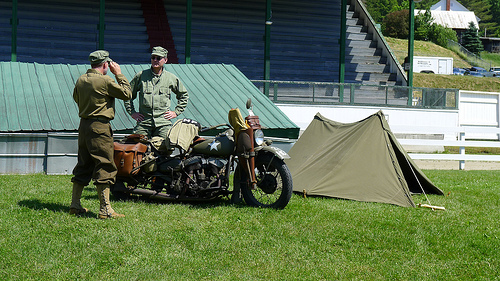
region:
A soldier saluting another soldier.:
[65, 46, 132, 217]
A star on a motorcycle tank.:
[207, 138, 220, 152]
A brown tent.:
[282, 108, 448, 215]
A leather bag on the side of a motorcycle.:
[109, 139, 147, 176]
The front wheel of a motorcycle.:
[241, 141, 292, 210]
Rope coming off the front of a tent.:
[389, 131, 434, 213]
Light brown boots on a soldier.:
[70, 179, 127, 218]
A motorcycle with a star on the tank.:
[112, 99, 293, 209]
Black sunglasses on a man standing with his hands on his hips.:
[148, 52, 163, 61]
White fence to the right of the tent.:
[381, 112, 498, 170]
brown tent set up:
[275, 110, 437, 210]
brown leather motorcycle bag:
[98, 138, 150, 174]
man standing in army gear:
[66, 42, 126, 226]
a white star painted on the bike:
[200, 132, 227, 158]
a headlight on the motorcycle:
[244, 115, 276, 151]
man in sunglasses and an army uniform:
[128, 45, 178, 140]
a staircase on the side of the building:
[336, 8, 413, 92]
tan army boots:
[62, 175, 120, 217]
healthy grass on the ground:
[188, 215, 408, 265]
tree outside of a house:
[455, 19, 488, 63]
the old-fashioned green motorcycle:
[112, 97, 305, 210]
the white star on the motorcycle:
[204, 140, 228, 155]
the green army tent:
[278, 106, 453, 219]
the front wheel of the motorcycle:
[231, 141, 296, 209]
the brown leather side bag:
[113, 141, 150, 180]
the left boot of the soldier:
[59, 166, 94, 223]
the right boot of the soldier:
[95, 181, 132, 223]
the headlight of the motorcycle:
[253, 127, 266, 151]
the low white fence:
[401, 124, 498, 174]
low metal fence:
[2, 128, 87, 170]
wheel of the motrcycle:
[244, 153, 299, 208]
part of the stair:
[311, 85, 317, 92]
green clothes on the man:
[66, 62, 124, 223]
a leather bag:
[105, 141, 147, 183]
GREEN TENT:
[297, 102, 423, 218]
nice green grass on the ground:
[252, 217, 370, 269]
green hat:
[148, 42, 168, 56]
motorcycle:
[176, 117, 307, 204]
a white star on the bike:
[201, 135, 227, 160]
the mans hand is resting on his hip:
[163, 107, 175, 119]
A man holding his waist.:
[124, 43, 190, 133]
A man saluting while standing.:
[70, 45, 134, 220]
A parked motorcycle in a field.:
[115, 110, 295, 212]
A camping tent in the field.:
[292, 104, 444, 204]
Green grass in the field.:
[4, 175, 494, 277]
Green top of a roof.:
[2, 59, 307, 135]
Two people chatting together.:
[69, 2, 191, 222]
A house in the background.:
[416, 0, 497, 76]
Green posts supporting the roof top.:
[9, 1, 420, 103]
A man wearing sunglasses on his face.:
[124, 45, 192, 137]